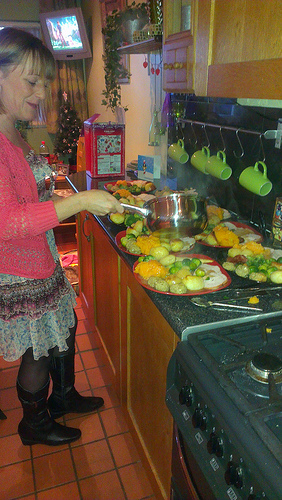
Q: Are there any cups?
A: Yes, there is a cup.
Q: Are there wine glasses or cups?
A: Yes, there is a cup.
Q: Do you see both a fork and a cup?
A: No, there is a cup but no forks.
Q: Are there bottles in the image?
A: No, there are no bottles.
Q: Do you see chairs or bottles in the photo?
A: No, there are no bottles or chairs.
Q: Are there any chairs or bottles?
A: No, there are no bottles or chairs.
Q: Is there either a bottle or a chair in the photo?
A: No, there are no bottles or chairs.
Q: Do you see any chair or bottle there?
A: No, there are no bottles or chairs.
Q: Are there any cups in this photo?
A: Yes, there is a cup.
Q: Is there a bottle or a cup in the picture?
A: Yes, there is a cup.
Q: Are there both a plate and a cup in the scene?
A: Yes, there are both a cup and a plate.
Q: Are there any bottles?
A: No, there are no bottles.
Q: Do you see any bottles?
A: No, there are no bottles.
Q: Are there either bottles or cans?
A: No, there are no bottles or cans.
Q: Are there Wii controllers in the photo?
A: No, there are no Wii controllers.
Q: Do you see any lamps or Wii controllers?
A: No, there are no Wii controllers or lamps.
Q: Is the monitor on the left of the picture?
A: Yes, the monitor is on the left of the image.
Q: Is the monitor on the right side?
A: No, the monitor is on the left of the image.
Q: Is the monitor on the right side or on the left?
A: The monitor is on the left of the image.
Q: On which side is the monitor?
A: The monitor is on the left of the image.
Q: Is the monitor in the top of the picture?
A: Yes, the monitor is in the top of the image.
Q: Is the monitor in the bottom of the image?
A: No, the monitor is in the top of the image.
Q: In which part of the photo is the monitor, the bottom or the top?
A: The monitor is in the top of the image.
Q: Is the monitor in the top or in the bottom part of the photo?
A: The monitor is in the top of the image.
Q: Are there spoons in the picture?
A: Yes, there is a spoon.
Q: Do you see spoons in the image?
A: Yes, there is a spoon.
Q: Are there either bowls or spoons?
A: Yes, there is a spoon.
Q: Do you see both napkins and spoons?
A: No, there is a spoon but no napkins.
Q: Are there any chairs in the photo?
A: No, there are no chairs.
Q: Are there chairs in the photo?
A: No, there are no chairs.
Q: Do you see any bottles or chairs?
A: No, there are no chairs or bottles.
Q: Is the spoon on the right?
A: Yes, the spoon is on the right of the image.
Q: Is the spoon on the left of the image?
A: No, the spoon is on the right of the image.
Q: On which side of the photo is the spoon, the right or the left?
A: The spoon is on the right of the image.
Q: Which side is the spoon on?
A: The spoon is on the right of the image.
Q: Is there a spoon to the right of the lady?
A: Yes, there is a spoon to the right of the lady.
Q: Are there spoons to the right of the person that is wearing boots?
A: Yes, there is a spoon to the right of the lady.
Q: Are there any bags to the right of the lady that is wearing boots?
A: No, there is a spoon to the right of the lady.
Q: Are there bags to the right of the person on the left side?
A: No, there is a spoon to the right of the lady.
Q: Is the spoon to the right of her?
A: Yes, the spoon is to the right of a lady.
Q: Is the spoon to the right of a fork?
A: No, the spoon is to the right of a lady.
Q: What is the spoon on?
A: The spoon is on the counter.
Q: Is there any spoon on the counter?
A: Yes, there is a spoon on the counter.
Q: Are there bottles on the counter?
A: No, there is a spoon on the counter.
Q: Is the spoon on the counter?
A: Yes, the spoon is on the counter.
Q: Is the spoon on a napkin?
A: No, the spoon is on the counter.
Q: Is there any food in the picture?
A: Yes, there is food.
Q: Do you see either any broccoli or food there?
A: Yes, there is food.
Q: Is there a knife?
A: No, there are no knives.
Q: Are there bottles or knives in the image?
A: No, there are no knives or bottles.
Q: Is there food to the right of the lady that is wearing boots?
A: Yes, there is food to the right of the lady.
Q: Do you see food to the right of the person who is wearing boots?
A: Yes, there is food to the right of the lady.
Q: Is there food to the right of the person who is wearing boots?
A: Yes, there is food to the right of the lady.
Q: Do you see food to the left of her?
A: No, the food is to the right of the lady.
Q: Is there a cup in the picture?
A: Yes, there is a cup.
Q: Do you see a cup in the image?
A: Yes, there is a cup.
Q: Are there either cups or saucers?
A: Yes, there is a cup.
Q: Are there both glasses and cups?
A: No, there is a cup but no glasses.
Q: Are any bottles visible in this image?
A: No, there are no bottles.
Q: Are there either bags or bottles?
A: No, there are no bottles or bags.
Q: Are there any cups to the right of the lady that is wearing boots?
A: Yes, there is a cup to the right of the lady.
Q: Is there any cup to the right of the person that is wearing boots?
A: Yes, there is a cup to the right of the lady.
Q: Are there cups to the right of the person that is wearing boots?
A: Yes, there is a cup to the right of the lady.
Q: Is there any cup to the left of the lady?
A: No, the cup is to the right of the lady.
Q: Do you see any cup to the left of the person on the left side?
A: No, the cup is to the right of the lady.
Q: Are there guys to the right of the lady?
A: No, there is a cup to the right of the lady.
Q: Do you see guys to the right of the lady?
A: No, there is a cup to the right of the lady.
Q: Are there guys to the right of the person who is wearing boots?
A: No, there is a cup to the right of the lady.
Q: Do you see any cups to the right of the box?
A: Yes, there is a cup to the right of the box.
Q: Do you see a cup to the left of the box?
A: No, the cup is to the right of the box.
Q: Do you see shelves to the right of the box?
A: No, there is a cup to the right of the box.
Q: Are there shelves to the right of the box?
A: No, there is a cup to the right of the box.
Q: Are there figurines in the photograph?
A: No, there are no figurines.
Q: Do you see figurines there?
A: No, there are no figurines.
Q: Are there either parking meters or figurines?
A: No, there are no figurines or parking meters.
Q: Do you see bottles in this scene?
A: No, there are no bottles.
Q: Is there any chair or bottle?
A: No, there are no bottles or chairs.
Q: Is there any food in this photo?
A: Yes, there is food.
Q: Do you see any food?
A: Yes, there is food.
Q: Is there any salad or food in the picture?
A: Yes, there is food.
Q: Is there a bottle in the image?
A: No, there are no bottles.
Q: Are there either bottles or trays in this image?
A: No, there are no bottles or trays.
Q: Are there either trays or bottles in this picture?
A: No, there are no bottles or trays.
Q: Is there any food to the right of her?
A: Yes, there is food to the right of the lady.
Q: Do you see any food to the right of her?
A: Yes, there is food to the right of the lady.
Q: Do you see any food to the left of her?
A: No, the food is to the right of the lady.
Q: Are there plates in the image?
A: Yes, there is a plate.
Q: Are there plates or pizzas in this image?
A: Yes, there is a plate.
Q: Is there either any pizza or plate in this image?
A: Yes, there is a plate.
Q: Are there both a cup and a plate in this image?
A: Yes, there are both a plate and a cup.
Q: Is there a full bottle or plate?
A: Yes, there is a full plate.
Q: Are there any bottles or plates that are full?
A: Yes, the plate is full.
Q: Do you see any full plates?
A: Yes, there is a full plate.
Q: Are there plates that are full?
A: Yes, there is a plate that is full.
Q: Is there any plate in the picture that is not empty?
A: Yes, there is an full plate.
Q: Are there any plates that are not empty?
A: Yes, there is an full plate.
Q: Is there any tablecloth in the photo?
A: No, there are no tablecloths.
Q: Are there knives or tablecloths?
A: No, there are no tablecloths or knives.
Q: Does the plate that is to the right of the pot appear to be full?
A: Yes, the plate is full.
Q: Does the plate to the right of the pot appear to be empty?
A: No, the plate is full.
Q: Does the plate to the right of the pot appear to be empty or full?
A: The plate is full.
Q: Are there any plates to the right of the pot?
A: Yes, there is a plate to the right of the pot.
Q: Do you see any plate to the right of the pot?
A: Yes, there is a plate to the right of the pot.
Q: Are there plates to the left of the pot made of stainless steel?
A: No, the plate is to the right of the pot.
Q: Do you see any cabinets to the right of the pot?
A: No, there is a plate to the right of the pot.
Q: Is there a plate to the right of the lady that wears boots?
A: Yes, there is a plate to the right of the lady.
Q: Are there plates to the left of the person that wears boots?
A: No, the plate is to the right of the lady.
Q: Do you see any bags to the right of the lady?
A: No, there is a plate to the right of the lady.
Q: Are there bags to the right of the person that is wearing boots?
A: No, there is a plate to the right of the lady.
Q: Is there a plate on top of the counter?
A: Yes, there is a plate on top of the counter.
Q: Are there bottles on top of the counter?
A: No, there is a plate on top of the counter.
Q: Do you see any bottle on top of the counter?
A: No, there is a plate on top of the counter.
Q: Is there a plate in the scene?
A: Yes, there is a plate.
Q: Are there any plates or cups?
A: Yes, there is a plate.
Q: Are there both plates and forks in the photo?
A: No, there is a plate but no forks.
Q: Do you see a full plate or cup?
A: Yes, there is a full plate.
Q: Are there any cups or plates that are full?
A: Yes, the plate is full.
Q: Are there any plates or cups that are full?
A: Yes, the plate is full.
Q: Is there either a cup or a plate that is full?
A: Yes, the plate is full.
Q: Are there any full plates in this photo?
A: Yes, there is a full plate.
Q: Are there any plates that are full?
A: Yes, there is a plate that is full.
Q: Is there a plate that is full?
A: Yes, there is a plate that is full.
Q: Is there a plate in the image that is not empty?
A: Yes, there is an full plate.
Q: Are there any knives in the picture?
A: No, there are no knives.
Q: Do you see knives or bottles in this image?
A: No, there are no knives or bottles.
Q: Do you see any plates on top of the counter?
A: Yes, there is a plate on top of the counter.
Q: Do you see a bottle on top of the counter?
A: No, there is a plate on top of the counter.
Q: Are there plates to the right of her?
A: Yes, there is a plate to the right of the lady.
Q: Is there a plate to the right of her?
A: Yes, there is a plate to the right of the lady.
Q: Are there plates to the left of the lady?
A: No, the plate is to the right of the lady.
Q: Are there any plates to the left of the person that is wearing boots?
A: No, the plate is to the right of the lady.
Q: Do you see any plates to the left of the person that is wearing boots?
A: No, the plate is to the right of the lady.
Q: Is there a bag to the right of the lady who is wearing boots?
A: No, there is a plate to the right of the lady.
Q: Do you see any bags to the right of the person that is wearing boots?
A: No, there is a plate to the right of the lady.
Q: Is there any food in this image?
A: Yes, there is food.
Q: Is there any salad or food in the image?
A: Yes, there is food.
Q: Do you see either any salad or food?
A: Yes, there is food.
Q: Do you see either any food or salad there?
A: Yes, there is food.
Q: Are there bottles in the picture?
A: No, there are no bottles.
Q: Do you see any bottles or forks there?
A: No, there are no bottles or forks.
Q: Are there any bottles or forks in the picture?
A: No, there are no bottles or forks.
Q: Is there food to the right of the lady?
A: Yes, there is food to the right of the lady.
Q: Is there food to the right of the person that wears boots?
A: Yes, there is food to the right of the lady.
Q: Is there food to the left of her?
A: No, the food is to the right of the lady.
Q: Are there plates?
A: Yes, there is a plate.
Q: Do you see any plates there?
A: Yes, there is a plate.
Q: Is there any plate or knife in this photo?
A: Yes, there is a plate.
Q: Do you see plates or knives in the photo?
A: Yes, there is a plate.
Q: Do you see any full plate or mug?
A: Yes, there is a full plate.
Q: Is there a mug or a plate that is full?
A: Yes, the plate is full.